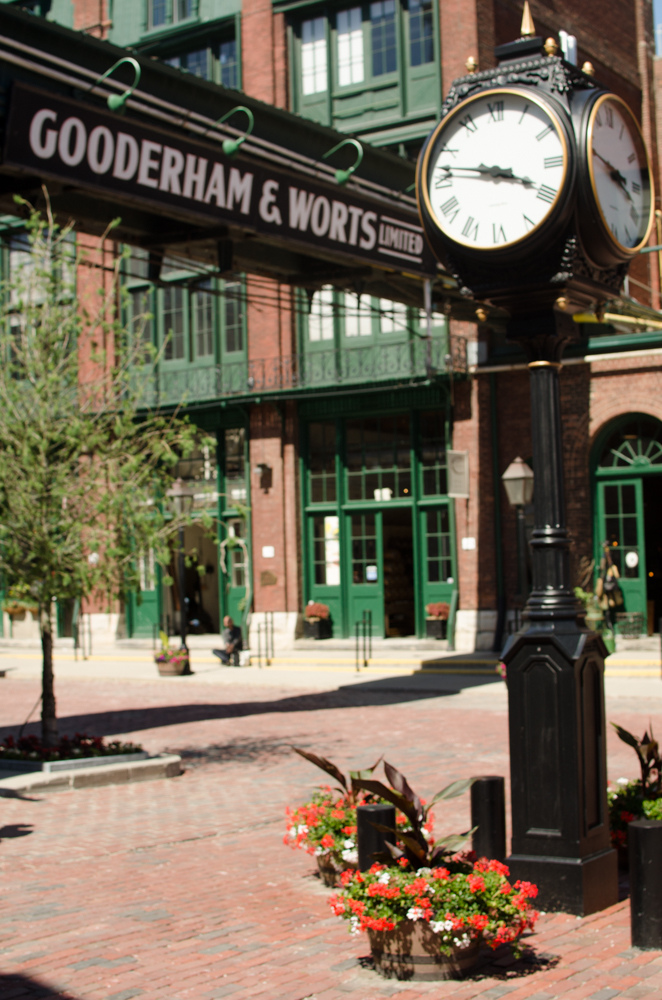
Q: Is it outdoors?
A: Yes, it is outdoors.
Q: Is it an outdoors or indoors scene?
A: It is outdoors.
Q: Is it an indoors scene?
A: No, it is outdoors.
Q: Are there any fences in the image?
A: No, there are no fences.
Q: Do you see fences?
A: No, there are no fences.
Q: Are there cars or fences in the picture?
A: No, there are no fences or cars.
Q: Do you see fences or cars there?
A: No, there are no fences or cars.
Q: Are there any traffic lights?
A: No, there are no traffic lights.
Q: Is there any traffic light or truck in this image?
A: No, there are no traffic lights or trucks.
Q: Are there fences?
A: No, there are no fences.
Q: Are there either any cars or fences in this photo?
A: No, there are no fences or cars.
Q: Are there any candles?
A: No, there are no candles.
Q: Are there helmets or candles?
A: No, there are no candles or helmets.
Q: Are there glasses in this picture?
A: No, there are no glasses.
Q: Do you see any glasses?
A: No, there are no glasses.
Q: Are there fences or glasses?
A: No, there are no glasses or fences.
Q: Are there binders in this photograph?
A: No, there are no binders.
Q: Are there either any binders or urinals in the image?
A: No, there are no binders or urinals.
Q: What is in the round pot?
A: The flowers are in the pot.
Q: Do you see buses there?
A: No, there are no buses.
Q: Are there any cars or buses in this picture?
A: No, there are no buses or cars.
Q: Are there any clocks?
A: Yes, there is a clock.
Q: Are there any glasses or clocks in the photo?
A: Yes, there is a clock.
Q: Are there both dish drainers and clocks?
A: No, there is a clock but no dish drainers.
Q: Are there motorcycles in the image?
A: No, there are no motorcycles.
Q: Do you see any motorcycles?
A: No, there are no motorcycles.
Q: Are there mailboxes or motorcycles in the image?
A: No, there are no motorcycles or mailboxes.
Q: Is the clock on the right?
A: Yes, the clock is on the right of the image.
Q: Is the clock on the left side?
A: No, the clock is on the right of the image.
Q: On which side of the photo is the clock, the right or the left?
A: The clock is on the right of the image.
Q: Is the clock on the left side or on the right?
A: The clock is on the right of the image.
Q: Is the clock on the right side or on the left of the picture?
A: The clock is on the right of the image.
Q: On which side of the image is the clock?
A: The clock is on the right of the image.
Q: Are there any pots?
A: Yes, there is a pot.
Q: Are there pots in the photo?
A: Yes, there is a pot.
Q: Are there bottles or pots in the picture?
A: Yes, there is a pot.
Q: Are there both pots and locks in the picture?
A: No, there is a pot but no locks.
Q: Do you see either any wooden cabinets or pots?
A: Yes, there is a wood pot.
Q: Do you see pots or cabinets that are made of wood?
A: Yes, the pot is made of wood.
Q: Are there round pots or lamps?
A: Yes, there is a round pot.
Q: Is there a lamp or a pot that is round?
A: Yes, the pot is round.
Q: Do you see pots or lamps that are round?
A: Yes, the pot is round.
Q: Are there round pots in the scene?
A: Yes, there is a round pot.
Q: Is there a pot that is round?
A: Yes, there is a pot that is round.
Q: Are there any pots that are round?
A: Yes, there is a pot that is round.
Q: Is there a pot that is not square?
A: Yes, there is a round pot.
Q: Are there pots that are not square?
A: Yes, there is a round pot.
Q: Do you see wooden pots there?
A: Yes, there is a wood pot.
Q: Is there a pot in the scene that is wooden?
A: Yes, there is a pot that is wooden.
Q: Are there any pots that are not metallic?
A: Yes, there is a wooden pot.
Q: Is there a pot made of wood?
A: Yes, there is a pot that is made of wood.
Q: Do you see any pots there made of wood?
A: Yes, there is a pot that is made of wood.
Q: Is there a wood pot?
A: Yes, there is a pot that is made of wood.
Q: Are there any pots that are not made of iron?
A: Yes, there is a pot that is made of wood.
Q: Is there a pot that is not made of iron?
A: Yes, there is a pot that is made of wood.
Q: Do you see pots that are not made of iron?
A: Yes, there is a pot that is made of wood.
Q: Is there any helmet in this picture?
A: No, there are no helmets.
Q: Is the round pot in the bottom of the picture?
A: Yes, the pot is in the bottom of the image.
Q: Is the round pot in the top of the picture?
A: No, the pot is in the bottom of the image.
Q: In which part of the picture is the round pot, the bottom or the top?
A: The pot is in the bottom of the image.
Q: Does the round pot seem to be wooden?
A: Yes, the pot is wooden.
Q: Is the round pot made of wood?
A: Yes, the pot is made of wood.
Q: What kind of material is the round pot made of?
A: The pot is made of wood.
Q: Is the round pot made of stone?
A: No, the pot is made of wood.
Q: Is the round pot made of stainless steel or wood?
A: The pot is made of wood.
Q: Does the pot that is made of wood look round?
A: Yes, the pot is round.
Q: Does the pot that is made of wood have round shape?
A: Yes, the pot is round.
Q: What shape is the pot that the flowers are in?
A: The pot is round.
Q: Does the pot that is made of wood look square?
A: No, the pot is round.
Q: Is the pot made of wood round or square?
A: The pot is round.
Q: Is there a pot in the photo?
A: Yes, there is a pot.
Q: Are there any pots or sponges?
A: Yes, there is a pot.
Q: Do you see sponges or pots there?
A: Yes, there is a pot.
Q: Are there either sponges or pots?
A: Yes, there is a pot.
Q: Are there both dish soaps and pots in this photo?
A: No, there is a pot but no dish soaps.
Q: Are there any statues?
A: No, there are no statues.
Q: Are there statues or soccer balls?
A: No, there are no statues or soccer balls.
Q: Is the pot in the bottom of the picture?
A: Yes, the pot is in the bottom of the image.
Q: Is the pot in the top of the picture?
A: No, the pot is in the bottom of the image.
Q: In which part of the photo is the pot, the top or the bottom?
A: The pot is in the bottom of the image.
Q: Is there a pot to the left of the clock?
A: Yes, there is a pot to the left of the clock.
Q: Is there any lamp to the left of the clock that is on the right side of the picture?
A: No, there is a pot to the left of the clock.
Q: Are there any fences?
A: No, there are no fences.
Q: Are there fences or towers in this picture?
A: No, there are no fences or towers.